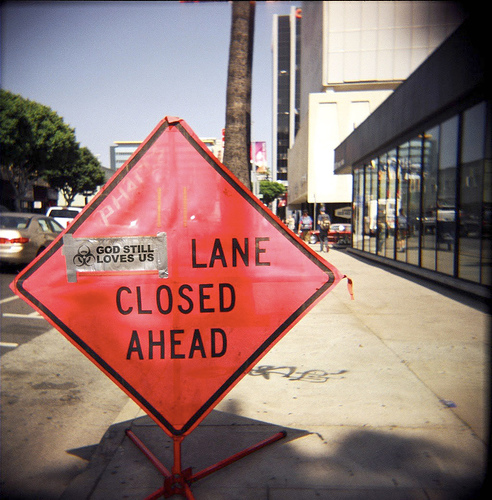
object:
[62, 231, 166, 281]
sticker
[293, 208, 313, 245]
people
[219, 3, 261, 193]
trunk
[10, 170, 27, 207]
trunk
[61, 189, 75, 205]
trunk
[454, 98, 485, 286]
windows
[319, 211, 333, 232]
backpack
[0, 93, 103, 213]
trees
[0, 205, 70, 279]
car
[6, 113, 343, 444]
warning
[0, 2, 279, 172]
sky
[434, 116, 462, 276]
windows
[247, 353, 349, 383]
graffiti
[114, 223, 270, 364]
lettering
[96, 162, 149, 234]
graffiti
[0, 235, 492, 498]
sidewalk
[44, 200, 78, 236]
truck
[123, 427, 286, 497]
base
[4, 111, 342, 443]
sign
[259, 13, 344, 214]
tall building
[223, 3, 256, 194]
tree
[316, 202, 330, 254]
people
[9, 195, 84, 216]
sidewalk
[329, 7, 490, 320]
building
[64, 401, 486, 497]
shadows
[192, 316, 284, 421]
border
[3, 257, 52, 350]
street